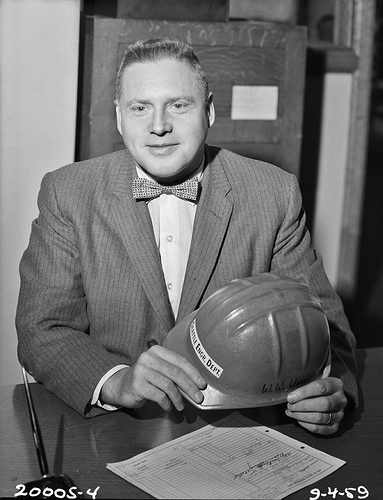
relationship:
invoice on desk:
[106, 409, 348, 499] [28, 365, 321, 499]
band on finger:
[311, 401, 336, 429] [286, 402, 350, 421]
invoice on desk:
[106, 409, 348, 499] [0, 344, 382, 499]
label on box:
[232, 68, 301, 125] [232, 25, 331, 145]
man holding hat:
[83, 26, 325, 344] [180, 294, 300, 374]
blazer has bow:
[15, 143, 361, 420] [132, 177, 199, 202]